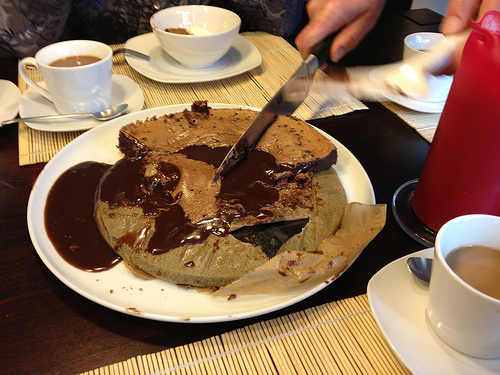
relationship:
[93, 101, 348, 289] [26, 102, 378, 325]
cake on top of plate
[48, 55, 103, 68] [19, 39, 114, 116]
coffe in cup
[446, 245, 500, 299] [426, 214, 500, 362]
coffe in cup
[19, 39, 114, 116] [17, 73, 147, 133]
cup on top of saucer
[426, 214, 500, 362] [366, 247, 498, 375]
cup on top of saucer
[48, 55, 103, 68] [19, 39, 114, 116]
coffee in cup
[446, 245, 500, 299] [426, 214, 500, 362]
coffee in cup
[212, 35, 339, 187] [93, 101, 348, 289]
knife cutting cake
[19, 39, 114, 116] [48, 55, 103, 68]
cup has coffee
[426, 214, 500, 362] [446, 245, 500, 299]
cup has coffee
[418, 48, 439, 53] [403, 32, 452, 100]
coffee in cup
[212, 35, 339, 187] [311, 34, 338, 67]
knife has handle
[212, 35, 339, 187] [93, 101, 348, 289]
knife cutting desert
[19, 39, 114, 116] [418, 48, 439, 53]
cup of coffee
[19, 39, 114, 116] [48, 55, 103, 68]
cup of coffee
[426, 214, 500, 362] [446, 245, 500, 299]
cup of coffee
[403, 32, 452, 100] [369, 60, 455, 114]
cup on top of saucer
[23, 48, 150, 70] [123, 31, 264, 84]
fork on top of saucer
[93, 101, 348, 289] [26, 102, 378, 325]
desert on top of plate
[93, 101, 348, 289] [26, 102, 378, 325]
fudge on top of plate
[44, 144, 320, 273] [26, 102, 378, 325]
chocolate on top of plate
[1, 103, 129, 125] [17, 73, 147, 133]
spoon on top of saucer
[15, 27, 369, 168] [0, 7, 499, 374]
placemat on top of table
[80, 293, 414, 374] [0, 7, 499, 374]
placemat on top of table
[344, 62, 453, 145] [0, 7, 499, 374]
placemat on top of table